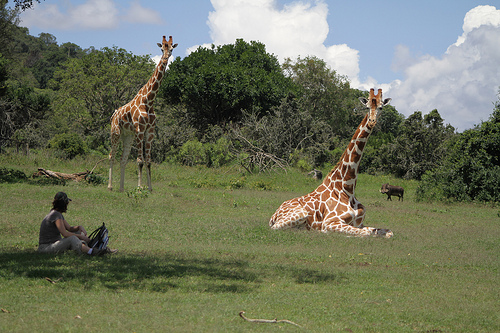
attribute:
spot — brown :
[332, 181, 342, 191]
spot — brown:
[335, 187, 368, 212]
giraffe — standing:
[79, 27, 191, 209]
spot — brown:
[130, 105, 135, 116]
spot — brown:
[320, 184, 337, 210]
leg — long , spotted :
[145, 125, 160, 190]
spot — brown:
[139, 96, 149, 105]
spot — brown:
[138, 104, 150, 111]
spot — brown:
[357, 127, 368, 141]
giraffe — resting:
[266, 85, 394, 241]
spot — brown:
[333, 203, 353, 213]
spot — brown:
[343, 163, 357, 180]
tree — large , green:
[158, 38, 305, 132]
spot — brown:
[319, 177, 332, 188]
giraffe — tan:
[103, 32, 178, 194]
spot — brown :
[331, 182, 351, 204]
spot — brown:
[307, 199, 323, 211]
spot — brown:
[329, 170, 344, 181]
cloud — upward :
[144, 0, 385, 97]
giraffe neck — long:
[272, 87, 407, 252]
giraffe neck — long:
[101, 26, 186, 200]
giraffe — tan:
[284, 64, 444, 261]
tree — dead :
[27, 148, 93, 188]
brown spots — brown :
[286, 191, 358, 236]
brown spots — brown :
[107, 59, 174, 172]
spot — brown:
[342, 139, 354, 153]